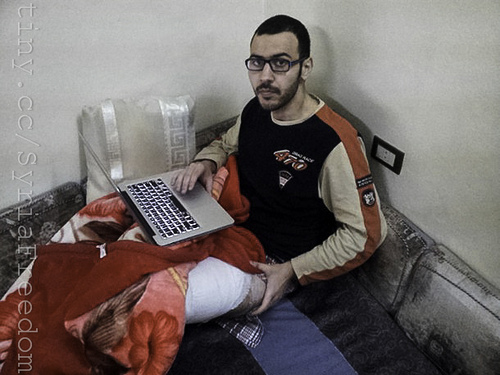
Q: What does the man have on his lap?
A: Laptop.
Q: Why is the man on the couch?
A: Injury.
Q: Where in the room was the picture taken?
A: Couch.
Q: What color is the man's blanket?
A: Red.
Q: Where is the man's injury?
A: Knee.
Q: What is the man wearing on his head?
A: Glasses.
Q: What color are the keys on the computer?
A: Black.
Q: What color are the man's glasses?
A: Black.